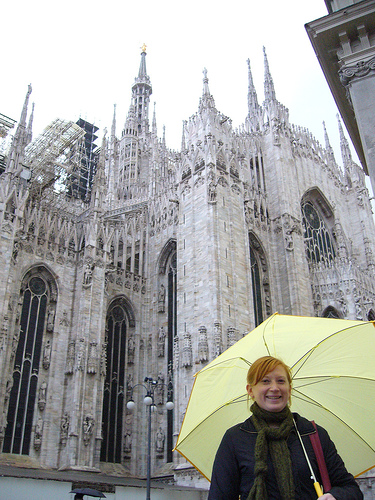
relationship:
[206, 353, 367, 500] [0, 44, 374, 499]
girl in front of building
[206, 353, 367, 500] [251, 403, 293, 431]
girl has neck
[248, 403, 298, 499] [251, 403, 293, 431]
scarf around neck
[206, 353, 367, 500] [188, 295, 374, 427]
girl holding umbrella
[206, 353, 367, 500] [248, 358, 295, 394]
girl with hair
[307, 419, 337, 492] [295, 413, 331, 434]
red strap on shoulder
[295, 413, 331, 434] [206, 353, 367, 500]
shoulder of girl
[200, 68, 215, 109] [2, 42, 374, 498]
point on building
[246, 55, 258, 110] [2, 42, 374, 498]
point on building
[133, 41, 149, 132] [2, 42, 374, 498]
point on building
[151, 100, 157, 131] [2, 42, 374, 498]
point on building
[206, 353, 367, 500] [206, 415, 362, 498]
girl wearing jacket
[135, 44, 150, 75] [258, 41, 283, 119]
spire on tower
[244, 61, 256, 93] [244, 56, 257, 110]
spire on tower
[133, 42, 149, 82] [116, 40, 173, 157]
spire on tower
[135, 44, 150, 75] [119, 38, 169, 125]
spire on tower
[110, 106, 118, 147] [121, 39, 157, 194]
spire on tower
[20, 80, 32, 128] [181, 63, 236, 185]
spire on tower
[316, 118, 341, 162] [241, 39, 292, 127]
spire on tower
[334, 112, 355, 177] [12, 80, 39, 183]
spire on tower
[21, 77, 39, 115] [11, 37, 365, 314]
spire on tower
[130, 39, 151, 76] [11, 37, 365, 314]
spire on tower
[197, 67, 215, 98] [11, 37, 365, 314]
spire on tower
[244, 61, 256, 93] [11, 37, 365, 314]
spire on tower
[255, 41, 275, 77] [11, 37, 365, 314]
spire on tower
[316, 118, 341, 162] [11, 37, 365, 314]
spire on tower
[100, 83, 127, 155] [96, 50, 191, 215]
spire on tower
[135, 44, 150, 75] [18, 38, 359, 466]
spire on tower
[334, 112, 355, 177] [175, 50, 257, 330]
spire on tower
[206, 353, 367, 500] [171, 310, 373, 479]
girl holding umbrella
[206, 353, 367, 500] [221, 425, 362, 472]
girl wearing jacket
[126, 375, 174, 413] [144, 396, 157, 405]
lamp with light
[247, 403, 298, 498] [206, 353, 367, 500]
scarf on girl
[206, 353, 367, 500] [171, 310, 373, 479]
girl holds umbrella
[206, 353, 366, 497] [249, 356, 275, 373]
girl has hair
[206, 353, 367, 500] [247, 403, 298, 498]
girl wearing scarf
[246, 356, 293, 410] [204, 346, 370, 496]
hair on woman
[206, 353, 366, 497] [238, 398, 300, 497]
girl wearing scarf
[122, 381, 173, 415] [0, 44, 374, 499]
lamp in front of building